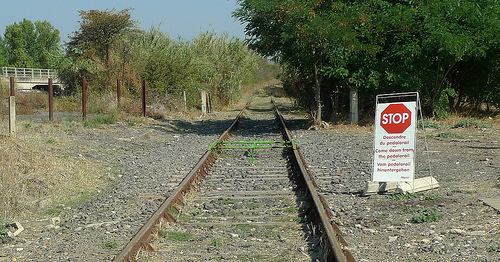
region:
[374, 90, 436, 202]
white and red stop sign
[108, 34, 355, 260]
long winding railroad tracks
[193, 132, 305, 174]
neon green railroad cart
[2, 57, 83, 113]
concrete bridge with railing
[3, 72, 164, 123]
rusted metal posts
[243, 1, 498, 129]
a lush green forest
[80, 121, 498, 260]
gray gravel rock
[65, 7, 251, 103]
brown green and white trees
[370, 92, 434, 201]
stop sign with red Spanish writing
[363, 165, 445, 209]
two blocks holding stop sign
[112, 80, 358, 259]
a railroad train track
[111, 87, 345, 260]
metal on top of the track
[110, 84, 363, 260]
wood on both sides of track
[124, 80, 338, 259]
wood bars between two metal rails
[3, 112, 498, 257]
an area of rocks and sand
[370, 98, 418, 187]
a white and red sign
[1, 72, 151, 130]
a line of wooden poles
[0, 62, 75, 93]
a bridge made from metal and concrete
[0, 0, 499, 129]
a bunch of green trees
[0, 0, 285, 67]
light blue sky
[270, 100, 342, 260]
one of the rails of the train track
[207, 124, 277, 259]
center of the railroad tracks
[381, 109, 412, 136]
stop sign next to the train tracks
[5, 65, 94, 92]
white bridge in the backdrop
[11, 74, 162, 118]
brown wooden posts by the tracks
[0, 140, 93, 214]
dry grass by the train tracks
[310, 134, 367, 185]
rocky ground by the train tracks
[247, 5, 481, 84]
green leaves on the trees by the tracks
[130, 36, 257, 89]
lighter green trees in the backdrop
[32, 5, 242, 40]
blue sky in the backdrop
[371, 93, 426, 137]
a stop sign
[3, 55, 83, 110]
a bridge with metal rails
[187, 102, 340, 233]
railroad tracks and wooden ties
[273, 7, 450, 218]
a sign beside railroad tracks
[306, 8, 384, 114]
deciduous tree with green leaves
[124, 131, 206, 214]
gravel beside a railroad track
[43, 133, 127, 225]
browning grass beside gravel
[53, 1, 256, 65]
tree tops and blue sky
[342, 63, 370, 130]
grey colored tree trunk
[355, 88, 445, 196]
metal framed sign holder